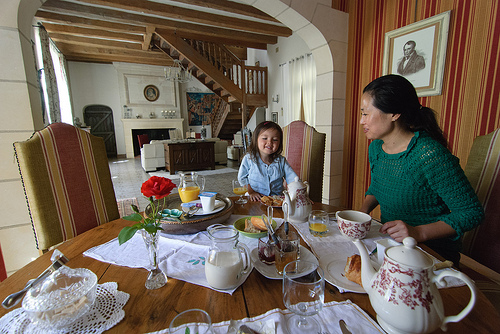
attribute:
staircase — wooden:
[174, 46, 254, 129]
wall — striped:
[340, 18, 380, 112]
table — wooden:
[66, 229, 161, 318]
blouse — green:
[362, 140, 463, 248]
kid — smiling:
[249, 120, 299, 165]